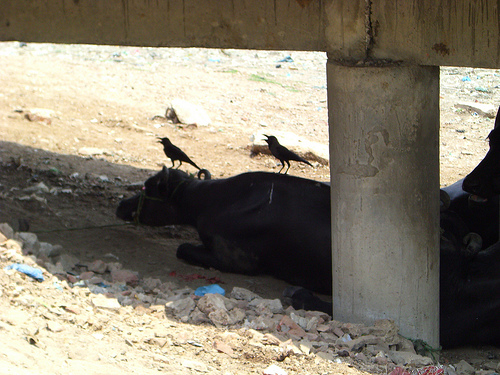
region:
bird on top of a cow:
[258, 127, 317, 179]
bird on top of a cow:
[149, 128, 210, 173]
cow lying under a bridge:
[100, 148, 346, 287]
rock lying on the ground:
[192, 288, 247, 328]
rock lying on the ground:
[104, 262, 146, 287]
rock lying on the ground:
[160, 287, 197, 326]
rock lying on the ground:
[365, 315, 402, 351]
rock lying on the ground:
[340, 328, 382, 350]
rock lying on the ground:
[275, 315, 312, 337]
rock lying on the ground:
[262, 362, 296, 374]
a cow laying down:
[72, 52, 499, 374]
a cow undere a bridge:
[69, 84, 498, 374]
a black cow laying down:
[62, 71, 498, 336]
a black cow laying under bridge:
[37, 3, 494, 371]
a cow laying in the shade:
[35, 8, 497, 361]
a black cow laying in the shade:
[32, 8, 432, 373]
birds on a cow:
[79, 76, 426, 321]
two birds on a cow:
[87, 83, 389, 240]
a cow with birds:
[83, 39, 421, 317]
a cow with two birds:
[107, 93, 404, 308]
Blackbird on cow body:
[255, 130, 312, 175]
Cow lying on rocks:
[110, 152, 490, 347]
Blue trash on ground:
[186, 275, 229, 301]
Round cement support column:
[311, 50, 462, 355]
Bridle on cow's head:
[130, 185, 162, 225]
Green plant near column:
[407, 333, 445, 363]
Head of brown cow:
[452, 101, 494, 197]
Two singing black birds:
[142, 123, 313, 180]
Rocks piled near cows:
[13, 230, 418, 372]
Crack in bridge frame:
[359, 3, 386, 72]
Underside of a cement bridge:
[0, 0, 497, 362]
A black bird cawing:
[153, 134, 201, 171]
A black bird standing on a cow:
[259, 131, 316, 182]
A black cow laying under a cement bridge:
[113, 162, 375, 309]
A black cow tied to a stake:
[16, 160, 358, 312]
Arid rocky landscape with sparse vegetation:
[1, 39, 498, 374]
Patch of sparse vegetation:
[227, 65, 294, 87]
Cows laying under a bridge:
[110, 94, 498, 363]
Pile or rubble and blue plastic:
[0, 225, 445, 371]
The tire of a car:
[441, 168, 496, 265]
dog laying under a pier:
[78, 141, 494, 329]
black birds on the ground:
[144, 128, 311, 173]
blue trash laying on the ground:
[173, 244, 263, 331]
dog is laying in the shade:
[90, 128, 438, 373]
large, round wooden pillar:
[305, 101, 473, 360]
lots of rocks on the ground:
[86, 257, 372, 374]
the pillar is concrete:
[318, 60, 443, 352]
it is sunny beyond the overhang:
[86, 74, 342, 208]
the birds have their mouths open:
[133, 110, 322, 204]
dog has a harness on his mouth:
[117, 171, 194, 239]